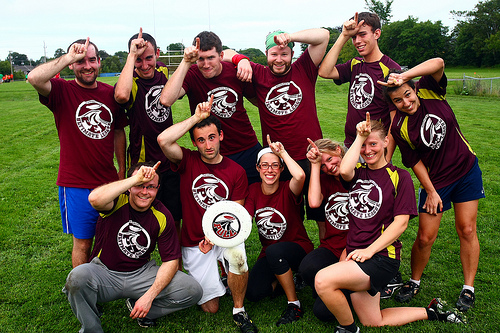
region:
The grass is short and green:
[10, 132, 57, 301]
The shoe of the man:
[225, 298, 266, 332]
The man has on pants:
[63, 258, 205, 331]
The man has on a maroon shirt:
[89, 193, 184, 277]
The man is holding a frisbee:
[201, 194, 252, 249]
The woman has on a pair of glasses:
[253, 155, 286, 175]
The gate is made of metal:
[452, 76, 491, 95]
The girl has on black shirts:
[343, 243, 406, 297]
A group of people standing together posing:
[23, 11, 485, 304]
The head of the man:
[183, 113, 228, 162]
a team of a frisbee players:
[27, 10, 492, 320]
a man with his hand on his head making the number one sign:
[63, 34, 105, 89]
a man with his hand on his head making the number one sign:
[126, 27, 159, 82]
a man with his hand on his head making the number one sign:
[183, 28, 228, 80]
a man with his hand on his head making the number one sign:
[259, 28, 296, 78]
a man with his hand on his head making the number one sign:
[343, 6, 383, 58]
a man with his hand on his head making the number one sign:
[124, 158, 164, 211]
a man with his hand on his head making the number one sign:
[188, 100, 228, 164]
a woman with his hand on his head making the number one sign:
[253, 134, 287, 190]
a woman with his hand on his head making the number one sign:
[373, 71, 426, 118]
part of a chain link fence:
[457, 73, 498, 95]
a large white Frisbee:
[200, 196, 257, 248]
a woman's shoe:
[427, 295, 464, 323]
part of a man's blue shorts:
[52, 187, 98, 239]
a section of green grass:
[449, 90, 497, 157]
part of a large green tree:
[442, 0, 497, 71]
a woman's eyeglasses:
[257, 160, 282, 172]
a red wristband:
[231, 49, 248, 66]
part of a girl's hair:
[305, 135, 344, 155]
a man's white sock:
[231, 305, 246, 314]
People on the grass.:
[13, 24, 403, 321]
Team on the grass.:
[34, 24, 493, 330]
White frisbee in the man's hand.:
[146, 177, 305, 280]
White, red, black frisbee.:
[175, 182, 295, 263]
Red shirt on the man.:
[42, 32, 179, 230]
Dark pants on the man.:
[257, 236, 344, 302]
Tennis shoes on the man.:
[398, 241, 474, 322]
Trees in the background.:
[341, 14, 496, 92]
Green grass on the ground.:
[12, 130, 113, 300]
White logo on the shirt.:
[68, 90, 140, 155]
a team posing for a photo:
[27, 12, 484, 329]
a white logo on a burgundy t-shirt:
[121, 220, 153, 260]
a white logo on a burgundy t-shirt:
[71, 98, 111, 146]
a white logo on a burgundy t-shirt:
[204, 83, 236, 125]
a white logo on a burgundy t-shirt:
[419, 114, 446, 153]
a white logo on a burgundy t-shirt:
[266, 80, 307, 128]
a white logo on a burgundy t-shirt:
[190, 171, 226, 203]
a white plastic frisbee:
[201, 197, 253, 246]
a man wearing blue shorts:
[29, 37, 103, 257]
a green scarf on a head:
[257, 34, 297, 48]